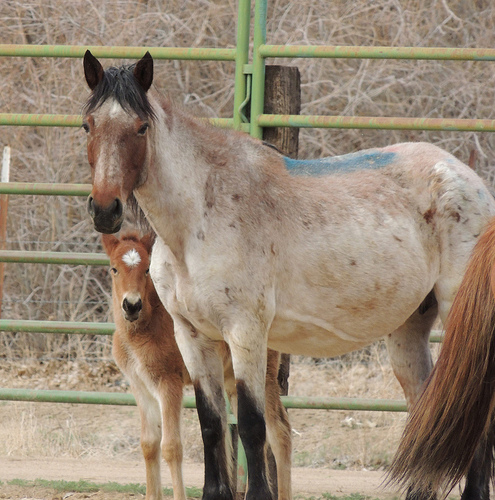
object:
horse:
[100, 229, 294, 499]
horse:
[79, 46, 494, 500]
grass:
[0, 479, 376, 498]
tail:
[374, 218, 495, 498]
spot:
[120, 246, 142, 267]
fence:
[0, 0, 494, 497]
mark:
[283, 145, 400, 176]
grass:
[0, 0, 494, 381]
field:
[0, 311, 494, 499]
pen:
[0, 0, 494, 498]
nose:
[119, 294, 145, 318]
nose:
[89, 199, 125, 231]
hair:
[80, 65, 160, 127]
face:
[104, 240, 161, 325]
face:
[76, 85, 152, 232]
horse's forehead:
[111, 239, 148, 271]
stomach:
[268, 278, 439, 360]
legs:
[155, 383, 189, 498]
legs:
[169, 305, 234, 498]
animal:
[374, 215, 494, 499]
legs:
[385, 296, 446, 498]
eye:
[106, 264, 119, 276]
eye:
[139, 266, 151, 275]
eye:
[77, 122, 87, 136]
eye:
[134, 120, 153, 140]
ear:
[102, 230, 121, 253]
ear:
[82, 48, 105, 90]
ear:
[133, 50, 155, 93]